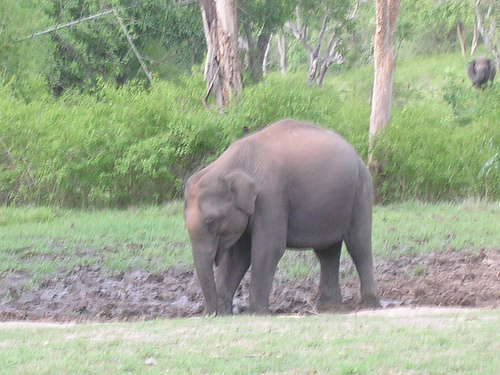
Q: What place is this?
A: It is a field.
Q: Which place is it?
A: It is a field.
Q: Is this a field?
A: Yes, it is a field.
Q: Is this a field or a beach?
A: It is a field.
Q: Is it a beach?
A: No, it is a field.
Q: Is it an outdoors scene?
A: Yes, it is outdoors.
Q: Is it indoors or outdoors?
A: It is outdoors.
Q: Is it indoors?
A: No, it is outdoors.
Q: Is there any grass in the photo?
A: Yes, there is grass.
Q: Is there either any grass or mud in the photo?
A: Yes, there is grass.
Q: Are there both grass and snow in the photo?
A: No, there is grass but no snow.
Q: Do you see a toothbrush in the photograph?
A: No, there are no toothbrushes.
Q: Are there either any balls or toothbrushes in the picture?
A: No, there are no toothbrushes or balls.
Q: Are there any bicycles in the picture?
A: No, there are no bicycles.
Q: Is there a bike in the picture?
A: No, there are no bikes.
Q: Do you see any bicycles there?
A: No, there are no bicycles.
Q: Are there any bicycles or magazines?
A: No, there are no bicycles or magazines.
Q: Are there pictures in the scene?
A: No, there are no pictures.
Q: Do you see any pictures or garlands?
A: No, there are no pictures or garlands.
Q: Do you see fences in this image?
A: No, there are no fences.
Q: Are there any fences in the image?
A: No, there are no fences.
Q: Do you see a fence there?
A: No, there are no fences.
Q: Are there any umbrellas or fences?
A: No, there are no fences or umbrellas.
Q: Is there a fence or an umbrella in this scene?
A: No, there are no fences or umbrellas.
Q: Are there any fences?
A: No, there are no fences.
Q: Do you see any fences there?
A: No, there are no fences.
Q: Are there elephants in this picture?
A: Yes, there is an elephant.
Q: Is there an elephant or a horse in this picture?
A: Yes, there is an elephant.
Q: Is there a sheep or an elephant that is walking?
A: Yes, the elephant is walking.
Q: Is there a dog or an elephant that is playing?
A: Yes, the elephant is playing.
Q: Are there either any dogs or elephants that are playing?
A: Yes, the elephant is playing.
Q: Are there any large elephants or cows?
A: Yes, there is a large elephant.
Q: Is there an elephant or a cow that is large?
A: Yes, the elephant is large.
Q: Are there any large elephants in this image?
A: Yes, there is a large elephant.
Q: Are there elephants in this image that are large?
A: Yes, there is an elephant that is large.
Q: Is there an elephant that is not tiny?
A: Yes, there is a large elephant.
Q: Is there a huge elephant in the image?
A: Yes, there is a huge elephant.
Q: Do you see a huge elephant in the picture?
A: Yes, there is a huge elephant.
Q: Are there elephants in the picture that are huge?
A: Yes, there is an elephant that is huge.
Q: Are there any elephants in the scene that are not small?
A: Yes, there is a huge elephant.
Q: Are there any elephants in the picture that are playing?
A: Yes, there is an elephant that is playing.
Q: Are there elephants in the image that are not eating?
A: Yes, there is an elephant that is playing.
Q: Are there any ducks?
A: No, there are no ducks.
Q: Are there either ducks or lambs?
A: No, there are no ducks or lambs.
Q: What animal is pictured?
A: The animal is an elephant.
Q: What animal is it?
A: The animal is an elephant.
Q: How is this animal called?
A: This is an elephant.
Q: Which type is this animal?
A: This is an elephant.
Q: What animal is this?
A: This is an elephant.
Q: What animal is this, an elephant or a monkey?
A: This is an elephant.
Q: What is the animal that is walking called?
A: The animal is an elephant.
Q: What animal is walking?
A: The animal is an elephant.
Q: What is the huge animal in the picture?
A: The animal is an elephant.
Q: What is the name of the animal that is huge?
A: The animal is an elephant.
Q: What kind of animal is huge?
A: The animal is an elephant.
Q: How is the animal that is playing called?
A: The animal is an elephant.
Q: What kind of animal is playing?
A: The animal is an elephant.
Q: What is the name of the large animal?
A: The animal is an elephant.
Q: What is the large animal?
A: The animal is an elephant.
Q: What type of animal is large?
A: The animal is an elephant.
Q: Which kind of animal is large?
A: The animal is an elephant.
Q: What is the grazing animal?
A: The animal is an elephant.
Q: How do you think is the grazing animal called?
A: The animal is an elephant.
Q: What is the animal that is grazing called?
A: The animal is an elephant.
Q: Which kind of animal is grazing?
A: The animal is an elephant.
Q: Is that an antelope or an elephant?
A: That is an elephant.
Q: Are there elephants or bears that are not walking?
A: No, there is an elephant but it is walking.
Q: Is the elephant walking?
A: Yes, the elephant is walking.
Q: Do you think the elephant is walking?
A: Yes, the elephant is walking.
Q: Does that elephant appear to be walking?
A: Yes, the elephant is walking.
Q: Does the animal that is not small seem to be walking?
A: Yes, the elephant is walking.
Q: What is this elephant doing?
A: The elephant is walking.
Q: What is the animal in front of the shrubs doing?
A: The elephant is walking.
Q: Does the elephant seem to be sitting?
A: No, the elephant is walking.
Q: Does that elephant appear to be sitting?
A: No, the elephant is walking.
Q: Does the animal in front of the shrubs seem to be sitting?
A: No, the elephant is walking.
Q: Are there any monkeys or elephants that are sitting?
A: No, there is an elephant but it is walking.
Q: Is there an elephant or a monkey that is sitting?
A: No, there is an elephant but it is walking.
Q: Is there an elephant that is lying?
A: No, there is an elephant but it is walking.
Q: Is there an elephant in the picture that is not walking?
A: No, there is an elephant but it is walking.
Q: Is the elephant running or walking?
A: The elephant is walking.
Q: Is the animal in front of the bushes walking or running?
A: The elephant is walking.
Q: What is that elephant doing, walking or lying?
A: The elephant is walking.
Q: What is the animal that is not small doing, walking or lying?
A: The elephant is walking.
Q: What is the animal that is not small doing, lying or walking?
A: The elephant is walking.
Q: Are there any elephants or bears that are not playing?
A: No, there is an elephant but it is playing.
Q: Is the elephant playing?
A: Yes, the elephant is playing.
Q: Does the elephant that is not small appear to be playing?
A: Yes, the elephant is playing.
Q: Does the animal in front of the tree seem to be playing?
A: Yes, the elephant is playing.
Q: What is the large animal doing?
A: The elephant is playing.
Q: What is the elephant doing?
A: The elephant is playing.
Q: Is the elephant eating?
A: No, the elephant is playing.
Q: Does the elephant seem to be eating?
A: No, the elephant is playing.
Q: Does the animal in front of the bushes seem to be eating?
A: No, the elephant is playing.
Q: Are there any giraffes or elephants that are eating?
A: No, there is an elephant but it is playing.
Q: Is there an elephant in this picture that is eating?
A: No, there is an elephant but it is playing.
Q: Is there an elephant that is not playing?
A: No, there is an elephant but it is playing.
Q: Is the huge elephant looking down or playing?
A: The elephant is playing.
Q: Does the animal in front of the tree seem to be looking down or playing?
A: The elephant is playing.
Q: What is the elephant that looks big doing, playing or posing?
A: The elephant is playing.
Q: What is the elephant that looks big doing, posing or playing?
A: The elephant is playing.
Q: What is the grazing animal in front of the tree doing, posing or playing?
A: The elephant is playing.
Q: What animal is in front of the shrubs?
A: The elephant is in front of the shrubs.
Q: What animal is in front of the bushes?
A: The elephant is in front of the shrubs.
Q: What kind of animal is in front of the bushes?
A: The animal is an elephant.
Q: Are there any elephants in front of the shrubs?
A: Yes, there is an elephant in front of the shrubs.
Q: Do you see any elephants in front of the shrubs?
A: Yes, there is an elephant in front of the shrubs.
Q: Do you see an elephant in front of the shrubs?
A: Yes, there is an elephant in front of the shrubs.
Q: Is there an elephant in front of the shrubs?
A: Yes, there is an elephant in front of the shrubs.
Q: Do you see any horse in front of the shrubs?
A: No, there is an elephant in front of the shrubs.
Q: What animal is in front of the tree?
A: The elephant is in front of the tree.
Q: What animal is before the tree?
A: The animal is an elephant.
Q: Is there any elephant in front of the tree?
A: Yes, there is an elephant in front of the tree.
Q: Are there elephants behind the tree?
A: No, the elephant is in front of the tree.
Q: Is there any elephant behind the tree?
A: No, the elephant is in front of the tree.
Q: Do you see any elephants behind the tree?
A: No, the elephant is in front of the tree.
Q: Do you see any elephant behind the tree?
A: No, the elephant is in front of the tree.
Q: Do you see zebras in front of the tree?
A: No, there is an elephant in front of the tree.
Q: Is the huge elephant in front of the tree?
A: Yes, the elephant is in front of the tree.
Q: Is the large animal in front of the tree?
A: Yes, the elephant is in front of the tree.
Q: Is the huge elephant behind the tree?
A: No, the elephant is in front of the tree.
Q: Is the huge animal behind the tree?
A: No, the elephant is in front of the tree.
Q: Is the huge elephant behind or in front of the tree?
A: The elephant is in front of the tree.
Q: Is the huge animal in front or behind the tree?
A: The elephant is in front of the tree.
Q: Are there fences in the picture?
A: No, there are no fences.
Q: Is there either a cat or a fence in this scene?
A: No, there are no fences or cats.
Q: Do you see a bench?
A: No, there are no benches.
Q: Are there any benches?
A: No, there are no benches.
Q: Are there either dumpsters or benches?
A: No, there are no benches or dumpsters.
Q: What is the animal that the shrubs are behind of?
A: The animal is an elephant.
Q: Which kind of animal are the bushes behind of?
A: The shrubs are behind the elephant.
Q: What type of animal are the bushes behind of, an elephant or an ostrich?
A: The bushes are behind an elephant.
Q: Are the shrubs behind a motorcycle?
A: No, the shrubs are behind the elephant.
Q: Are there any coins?
A: No, there are no coins.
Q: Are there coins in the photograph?
A: No, there are no coins.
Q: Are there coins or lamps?
A: No, there are no coins or lamps.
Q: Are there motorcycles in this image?
A: No, there are no motorcycles.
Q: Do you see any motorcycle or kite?
A: No, there are no motorcycles or kites.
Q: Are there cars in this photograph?
A: No, there are no cars.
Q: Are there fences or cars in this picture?
A: No, there are no cars or fences.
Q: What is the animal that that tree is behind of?
A: The animal is an elephant.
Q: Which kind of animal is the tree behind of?
A: The tree is behind the elephant.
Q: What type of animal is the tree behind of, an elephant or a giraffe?
A: The tree is behind an elephant.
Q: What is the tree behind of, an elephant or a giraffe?
A: The tree is behind an elephant.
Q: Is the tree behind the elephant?
A: Yes, the tree is behind the elephant.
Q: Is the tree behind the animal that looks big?
A: Yes, the tree is behind the elephant.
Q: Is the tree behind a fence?
A: No, the tree is behind the elephant.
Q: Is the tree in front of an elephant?
A: No, the tree is behind an elephant.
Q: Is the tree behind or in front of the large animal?
A: The tree is behind the elephant.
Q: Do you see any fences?
A: No, there are no fences.